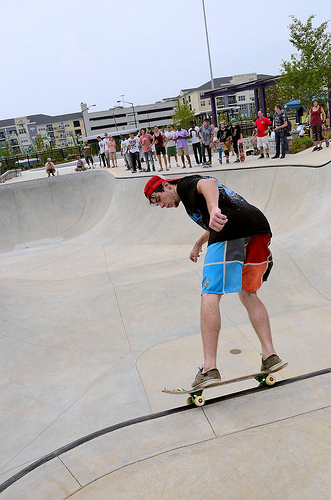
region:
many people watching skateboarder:
[42, 103, 318, 189]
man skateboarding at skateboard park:
[139, 161, 285, 407]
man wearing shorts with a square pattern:
[197, 225, 292, 299]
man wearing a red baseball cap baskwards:
[138, 170, 183, 211]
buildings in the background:
[28, 69, 298, 155]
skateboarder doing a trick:
[148, 159, 287, 401]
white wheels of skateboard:
[182, 395, 207, 410]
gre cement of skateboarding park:
[39, 204, 118, 337]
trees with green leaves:
[275, 19, 328, 131]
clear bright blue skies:
[50, 17, 165, 83]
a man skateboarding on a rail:
[144, 172, 290, 405]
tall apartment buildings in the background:
[0, 72, 86, 154]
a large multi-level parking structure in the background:
[79, 99, 185, 136]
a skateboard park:
[0, 152, 330, 498]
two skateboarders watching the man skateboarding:
[217, 117, 246, 162]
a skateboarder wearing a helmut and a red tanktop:
[308, 97, 329, 152]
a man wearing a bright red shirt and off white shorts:
[252, 109, 272, 159]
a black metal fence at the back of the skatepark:
[0, 141, 104, 173]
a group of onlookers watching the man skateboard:
[31, 98, 326, 173]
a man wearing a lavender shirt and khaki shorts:
[175, 122, 193, 167]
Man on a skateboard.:
[126, 172, 309, 403]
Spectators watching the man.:
[35, 84, 330, 174]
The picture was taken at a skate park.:
[5, 5, 325, 498]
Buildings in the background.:
[0, 66, 271, 159]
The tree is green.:
[298, 38, 329, 84]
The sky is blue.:
[16, 8, 111, 61]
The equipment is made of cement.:
[1, 187, 118, 328]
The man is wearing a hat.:
[137, 163, 178, 203]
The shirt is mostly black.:
[183, 183, 246, 230]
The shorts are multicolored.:
[198, 238, 274, 285]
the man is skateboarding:
[129, 168, 292, 415]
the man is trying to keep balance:
[133, 164, 288, 425]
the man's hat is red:
[136, 173, 178, 211]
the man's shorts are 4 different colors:
[195, 225, 275, 305]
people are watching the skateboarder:
[29, 95, 325, 186]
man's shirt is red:
[251, 114, 276, 146]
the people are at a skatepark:
[2, 2, 330, 491]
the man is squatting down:
[33, 153, 61, 176]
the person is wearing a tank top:
[301, 95, 327, 132]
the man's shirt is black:
[174, 173, 279, 243]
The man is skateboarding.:
[133, 165, 295, 403]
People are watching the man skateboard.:
[39, 92, 322, 168]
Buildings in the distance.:
[2, 61, 320, 152]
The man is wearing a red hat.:
[131, 168, 185, 214]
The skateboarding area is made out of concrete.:
[5, 168, 327, 445]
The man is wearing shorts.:
[191, 227, 278, 298]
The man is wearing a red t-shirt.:
[246, 103, 273, 159]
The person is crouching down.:
[34, 151, 60, 180]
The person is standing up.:
[133, 121, 154, 171]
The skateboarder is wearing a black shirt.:
[174, 161, 283, 240]